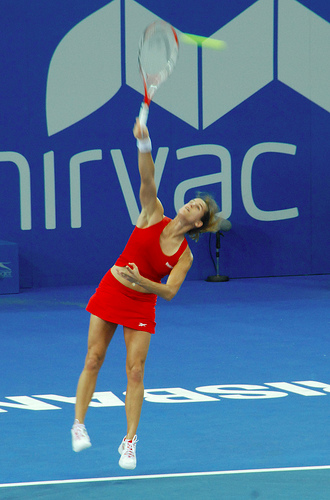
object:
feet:
[113, 424, 149, 470]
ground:
[0, 271, 329, 500]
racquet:
[135, 12, 183, 128]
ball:
[177, 27, 234, 52]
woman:
[61, 102, 232, 469]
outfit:
[84, 214, 190, 336]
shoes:
[67, 417, 96, 457]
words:
[1, 134, 313, 239]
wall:
[0, 0, 328, 282]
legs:
[70, 310, 119, 432]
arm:
[126, 120, 163, 211]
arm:
[117, 251, 196, 303]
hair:
[186, 190, 234, 245]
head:
[179, 192, 219, 239]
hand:
[128, 118, 156, 150]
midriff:
[110, 259, 152, 294]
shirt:
[113, 214, 190, 290]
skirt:
[83, 266, 159, 339]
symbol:
[162, 259, 177, 270]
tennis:
[5, 5, 321, 499]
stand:
[204, 228, 232, 285]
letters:
[234, 132, 312, 245]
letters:
[190, 380, 290, 412]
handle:
[135, 102, 150, 131]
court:
[3, 279, 328, 499]